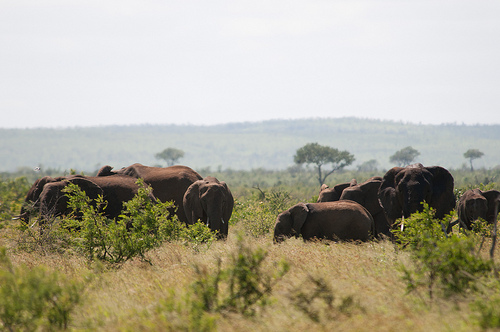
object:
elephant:
[379, 165, 456, 232]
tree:
[293, 142, 357, 189]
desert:
[0, 168, 500, 332]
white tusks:
[206, 216, 226, 228]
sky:
[0, 0, 500, 130]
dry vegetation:
[65, 236, 455, 331]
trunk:
[206, 204, 224, 234]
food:
[10, 217, 97, 262]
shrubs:
[1, 228, 500, 332]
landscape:
[0, 117, 500, 332]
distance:
[0, 117, 500, 174]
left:
[0, 0, 30, 331]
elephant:
[183, 176, 235, 241]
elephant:
[272, 200, 375, 245]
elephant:
[37, 178, 104, 229]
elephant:
[96, 162, 205, 228]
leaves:
[430, 243, 459, 269]